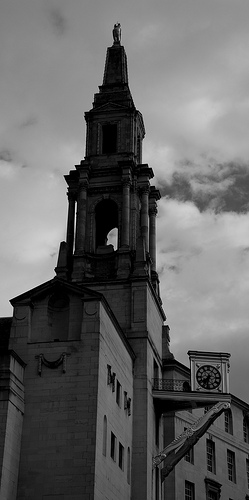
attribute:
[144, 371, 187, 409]
fence — black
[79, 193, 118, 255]
arches — open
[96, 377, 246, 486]
windows — arched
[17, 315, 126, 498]
wall — brick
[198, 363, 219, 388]
clock — white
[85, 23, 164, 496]
tower — black-and-white, tall, brick, old, stone